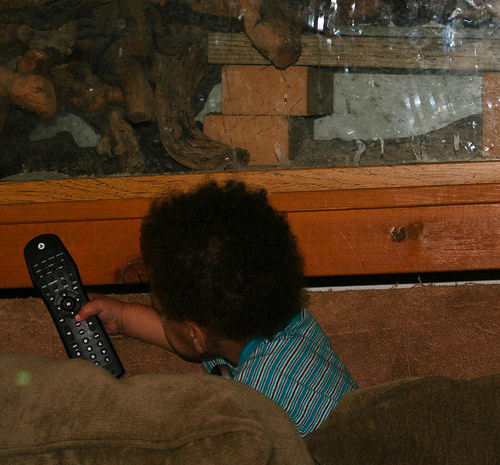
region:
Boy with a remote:
[13, 207, 414, 447]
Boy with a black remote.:
[16, 149, 471, 431]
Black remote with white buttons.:
[21, 211, 123, 411]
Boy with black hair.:
[128, 117, 438, 400]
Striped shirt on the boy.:
[185, 305, 391, 447]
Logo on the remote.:
[26, 230, 73, 282]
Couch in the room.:
[19, 334, 307, 464]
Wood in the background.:
[240, 37, 499, 327]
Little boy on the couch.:
[8, 168, 409, 444]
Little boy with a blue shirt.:
[43, 153, 353, 373]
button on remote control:
[103, 355, 112, 364]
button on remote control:
[99, 348, 106, 356]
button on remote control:
[87, 349, 97, 361]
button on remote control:
[72, 348, 83, 358]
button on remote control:
[70, 341, 78, 349]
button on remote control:
[80, 337, 90, 346]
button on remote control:
[90, 331, 100, 341]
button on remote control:
[85, 319, 96, 329]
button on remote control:
[64, 327, 73, 337]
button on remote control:
[45, 293, 57, 304]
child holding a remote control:
[9, 184, 364, 432]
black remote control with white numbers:
[31, 220, 124, 387]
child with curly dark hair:
[136, 167, 296, 358]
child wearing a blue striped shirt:
[235, 318, 347, 458]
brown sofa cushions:
[26, 349, 488, 461]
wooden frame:
[9, 147, 479, 304]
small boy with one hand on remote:
[16, 154, 373, 436]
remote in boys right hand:
[23, 218, 108, 396]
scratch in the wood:
[319, 221, 372, 268]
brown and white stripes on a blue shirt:
[248, 316, 376, 436]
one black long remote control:
[21, 227, 124, 377]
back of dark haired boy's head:
[127, 176, 306, 362]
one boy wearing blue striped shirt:
[139, 184, 353, 436]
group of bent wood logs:
[11, 13, 237, 172]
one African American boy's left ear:
[185, 317, 211, 362]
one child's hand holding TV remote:
[21, 229, 142, 391]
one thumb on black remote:
[71, 299, 96, 344]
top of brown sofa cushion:
[6, 355, 306, 464]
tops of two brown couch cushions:
[27, 362, 489, 456]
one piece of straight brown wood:
[203, 19, 498, 79]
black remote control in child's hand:
[17, 227, 132, 384]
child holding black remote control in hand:
[19, 173, 366, 443]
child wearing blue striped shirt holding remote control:
[18, 153, 368, 443]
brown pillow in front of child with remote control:
[2, 342, 319, 460]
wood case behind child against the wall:
[1, 151, 497, 297]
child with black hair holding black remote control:
[18, 163, 364, 444]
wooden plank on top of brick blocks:
[202, 25, 499, 70]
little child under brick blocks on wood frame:
[71, 172, 372, 439]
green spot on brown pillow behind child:
[10, 360, 37, 392]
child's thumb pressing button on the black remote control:
[68, 293, 113, 330]